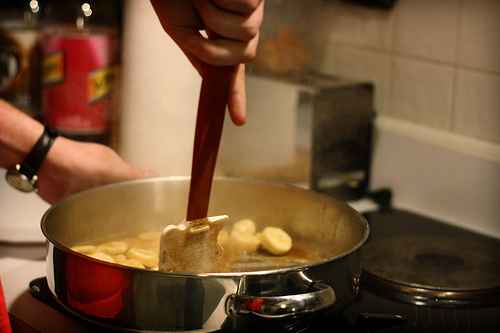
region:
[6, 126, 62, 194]
a black wrist watch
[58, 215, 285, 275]
some sliced pieces of banana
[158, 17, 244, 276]
a broken rubber spatula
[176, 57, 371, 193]
a shiny silver toaster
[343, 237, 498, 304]
a burner on a stove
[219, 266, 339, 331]
a shiny silver handle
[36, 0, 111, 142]
a pink bottle of soda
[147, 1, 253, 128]
the hand of a person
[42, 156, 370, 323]
a silvery round pan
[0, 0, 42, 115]
another bottle of liquid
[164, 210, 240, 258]
white part of wooden spatula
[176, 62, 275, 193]
wooden handle of brown spatula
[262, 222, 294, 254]
large white cut banana in pot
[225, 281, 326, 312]
silver handle of cooking skillet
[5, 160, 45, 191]
silver face of black watch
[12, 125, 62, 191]
black watch on person's hand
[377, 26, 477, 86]
white tile on wall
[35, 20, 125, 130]
tin can with red label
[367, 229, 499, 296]
silver cover on stove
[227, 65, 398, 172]
silver microwave on counter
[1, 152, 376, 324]
food is being cooked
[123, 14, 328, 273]
the spoon is made of wood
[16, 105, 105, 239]
the person is wearing a watch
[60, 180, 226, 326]
reflection is cast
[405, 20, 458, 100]
the wall is made of tiles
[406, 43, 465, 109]
the tiles are white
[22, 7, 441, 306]
this is an indoor scene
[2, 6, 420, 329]
it is in a kitchen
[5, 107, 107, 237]
the watch is black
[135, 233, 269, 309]
reflection is cast on the pan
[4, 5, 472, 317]
person cooking at home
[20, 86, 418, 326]
stainless steel pan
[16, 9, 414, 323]
person using rubber spatula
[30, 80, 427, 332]
steaming of potatoes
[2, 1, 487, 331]
bottles of soda in the background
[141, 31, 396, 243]
toaster in the background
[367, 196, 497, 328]
pot lid on top of stove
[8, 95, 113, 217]
person wearing a watch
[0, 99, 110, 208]
watch with black leather band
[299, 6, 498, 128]
tiled wall in the background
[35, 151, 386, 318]
a stainless steel pot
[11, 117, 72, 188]
a brown leather watch band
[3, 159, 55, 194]
a round watch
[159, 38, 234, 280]
a heat resistant rubber spatula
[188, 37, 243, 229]
a red plastic handle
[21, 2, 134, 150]
a red and yellow label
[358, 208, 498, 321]
an electrical stove top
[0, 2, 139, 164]
bottles of non alcoholic beverages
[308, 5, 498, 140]
white tile back splash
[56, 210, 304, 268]
bananas cooking in a pot